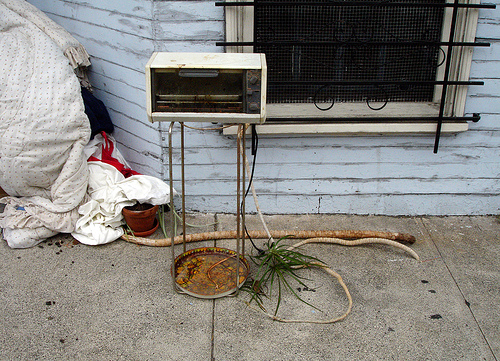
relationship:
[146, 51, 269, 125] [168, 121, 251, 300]
toaster oven sitting on plant stand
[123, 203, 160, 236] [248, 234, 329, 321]
pot for plant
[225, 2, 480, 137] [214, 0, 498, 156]
window covered with security bars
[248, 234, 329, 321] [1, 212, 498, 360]
plant laying on sidewalk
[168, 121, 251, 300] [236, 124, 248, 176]
plant stand has rust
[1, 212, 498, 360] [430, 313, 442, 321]
sidewalk has stain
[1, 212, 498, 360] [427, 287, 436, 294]
sidewalk has stain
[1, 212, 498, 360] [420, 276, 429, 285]
sidewalk has stain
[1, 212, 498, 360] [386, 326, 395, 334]
sidewalk has stain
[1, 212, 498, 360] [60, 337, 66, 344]
sidewalk has stain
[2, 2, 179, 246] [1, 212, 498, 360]
clothing on sidewalk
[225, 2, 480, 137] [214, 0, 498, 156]
window has security bars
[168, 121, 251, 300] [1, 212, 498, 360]
plant stand on sidewalk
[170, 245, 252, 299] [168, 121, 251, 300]
tray under plant stand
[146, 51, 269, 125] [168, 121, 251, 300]
toaster oven sitting in plant stand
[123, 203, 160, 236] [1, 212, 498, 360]
pot on ground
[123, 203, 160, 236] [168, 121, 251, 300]
pot beside plant stand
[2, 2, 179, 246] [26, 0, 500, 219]
clothing against house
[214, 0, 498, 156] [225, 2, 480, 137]
security bars on window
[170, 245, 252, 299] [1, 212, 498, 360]
tray on sidewalk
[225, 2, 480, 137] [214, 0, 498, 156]
window covered in security bars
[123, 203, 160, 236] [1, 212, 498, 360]
pot on sidewalk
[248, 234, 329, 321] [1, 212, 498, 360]
plant on sidewalk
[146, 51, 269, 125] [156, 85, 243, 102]
toaster oven has sheet